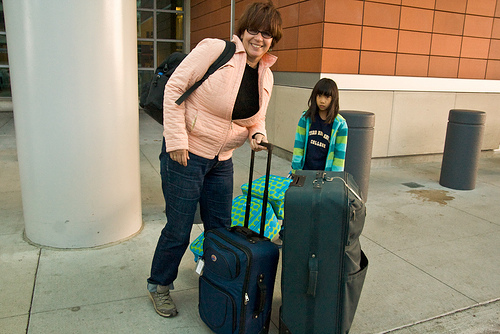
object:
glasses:
[242, 22, 275, 39]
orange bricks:
[354, 12, 450, 81]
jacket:
[163, 36, 274, 163]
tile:
[396, 3, 436, 30]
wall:
[185, 0, 499, 166]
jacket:
[290, 112, 347, 174]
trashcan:
[437, 107, 485, 191]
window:
[158, 12, 188, 39]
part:
[371, 150, 500, 334]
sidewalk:
[1, 155, 498, 332]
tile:
[427, 54, 461, 79]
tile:
[457, 55, 489, 78]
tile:
[460, 13, 494, 39]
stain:
[407, 182, 454, 211]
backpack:
[142, 38, 234, 127]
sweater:
[290, 110, 347, 172]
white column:
[1, 0, 140, 248]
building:
[138, 0, 499, 163]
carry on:
[195, 133, 284, 334]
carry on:
[279, 168, 368, 334]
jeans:
[145, 136, 234, 293]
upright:
[277, 168, 369, 334]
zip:
[212, 53, 278, 161]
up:
[143, 241, 192, 319]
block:
[319, 20, 364, 53]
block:
[359, 21, 401, 54]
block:
[395, 28, 432, 57]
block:
[357, 49, 397, 76]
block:
[393, 50, 431, 76]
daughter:
[291, 76, 347, 180]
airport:
[0, 1, 500, 334]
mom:
[138, 2, 287, 317]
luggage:
[195, 140, 278, 331]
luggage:
[277, 167, 368, 334]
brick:
[319, 19, 362, 50]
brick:
[318, 45, 361, 74]